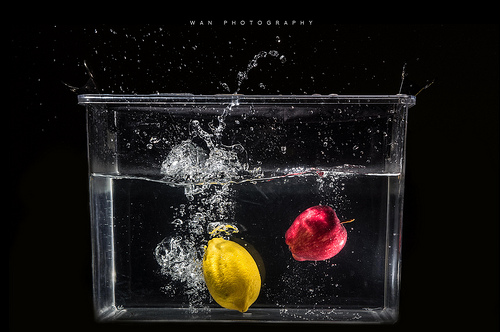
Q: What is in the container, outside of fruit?
A: Water.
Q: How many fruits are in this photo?
A: Two.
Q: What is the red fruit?
A: An apple.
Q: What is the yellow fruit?
A: A lemon.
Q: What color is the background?
A: Black.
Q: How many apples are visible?
A: One.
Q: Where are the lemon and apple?
A: In the water.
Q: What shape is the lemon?
A: Oval.